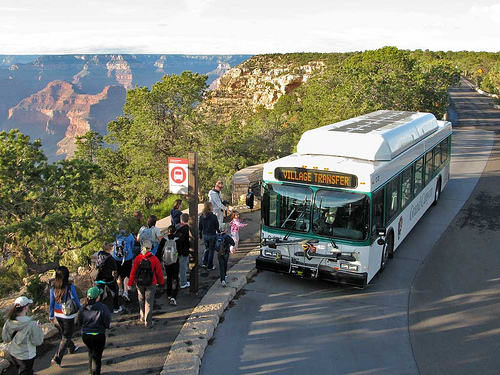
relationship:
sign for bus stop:
[168, 157, 200, 197] [52, 195, 270, 358]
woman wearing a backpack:
[126, 244, 167, 324] [137, 260, 153, 285]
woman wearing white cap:
[8, 298, 40, 374] [14, 295, 32, 309]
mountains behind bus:
[3, 59, 233, 172] [260, 108, 450, 287]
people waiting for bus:
[6, 201, 244, 358] [260, 108, 450, 287]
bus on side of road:
[260, 108, 450, 287] [225, 71, 499, 374]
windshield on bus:
[265, 182, 367, 238] [260, 108, 450, 287]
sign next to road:
[168, 157, 200, 197] [225, 71, 499, 374]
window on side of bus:
[389, 180, 397, 216] [260, 108, 450, 287]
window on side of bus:
[401, 168, 411, 202] [260, 108, 450, 287]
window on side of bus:
[415, 162, 424, 185] [260, 108, 450, 287]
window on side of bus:
[426, 153, 433, 177] [260, 108, 450, 287]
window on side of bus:
[435, 147, 438, 168] [260, 108, 450, 287]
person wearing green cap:
[80, 286, 109, 374] [88, 285, 101, 297]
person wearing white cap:
[8, 298, 40, 374] [14, 295, 32, 309]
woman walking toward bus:
[126, 244, 167, 324] [260, 108, 450, 287]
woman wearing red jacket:
[126, 244, 167, 324] [129, 255, 165, 286]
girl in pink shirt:
[229, 212, 243, 248] [231, 217, 239, 231]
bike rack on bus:
[261, 235, 358, 273] [260, 108, 450, 287]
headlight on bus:
[339, 262, 362, 272] [260, 108, 450, 287]